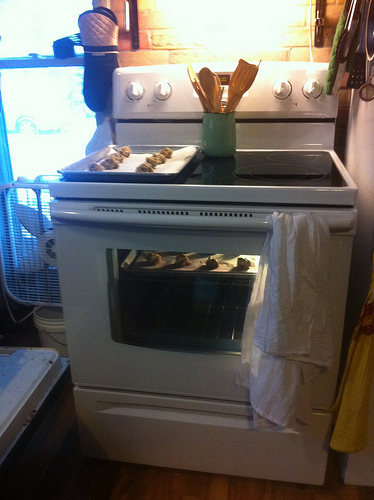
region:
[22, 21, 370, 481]
picture taken indoors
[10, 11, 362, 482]
picture taken during the day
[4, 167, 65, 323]
a stand along fan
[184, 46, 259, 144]
wood utensils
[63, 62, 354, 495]
a white stove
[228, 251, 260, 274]
the stove light is on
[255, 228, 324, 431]
a white towel on the stove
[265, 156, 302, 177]
a black oven surface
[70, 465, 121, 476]
the floor is made of wood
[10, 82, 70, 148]
the light is coming in through the window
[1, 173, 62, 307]
white box fan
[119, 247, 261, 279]
raw cookie dough on a tray in the oven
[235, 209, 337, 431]
white towel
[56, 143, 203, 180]
tray with raw cookie dough on the stovetop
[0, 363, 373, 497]
dark wooden floor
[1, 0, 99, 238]
long kitchen window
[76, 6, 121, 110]
black and white oven mitt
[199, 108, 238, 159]
green enamel utensil holder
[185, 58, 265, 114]
wooden kitchen utensils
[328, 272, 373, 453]
yellow kitchen towel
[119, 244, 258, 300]
cookie doughs in the oven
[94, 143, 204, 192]
cookie doughs on the tray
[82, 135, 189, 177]
cookie doughs on the tray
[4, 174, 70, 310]
A white boxed fan.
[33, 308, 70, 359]
A white bucket.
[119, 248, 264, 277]
A grey pan.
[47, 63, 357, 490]
A white stove set.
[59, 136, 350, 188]
A black stovetop.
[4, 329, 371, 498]
Hardwood floors.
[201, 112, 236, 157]
A green container.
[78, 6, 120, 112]
An oven mit.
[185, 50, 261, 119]
Wooden kitchen utensils.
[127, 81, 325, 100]
White knobs on a stove.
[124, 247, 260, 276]
Cookies baking in the oven.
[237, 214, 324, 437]
White towel on oven door.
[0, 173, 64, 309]
Fan by the window.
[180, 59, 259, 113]
Wooden kitchen utensils.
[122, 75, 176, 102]
White knobs on front of oven.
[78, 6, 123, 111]
Oven mitt on wall.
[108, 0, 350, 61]
Bricks on the wall.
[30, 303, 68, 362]
White bucket under fan.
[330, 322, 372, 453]
Yellow towel hanging from cabinet.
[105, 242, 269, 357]
Window in the oven door.